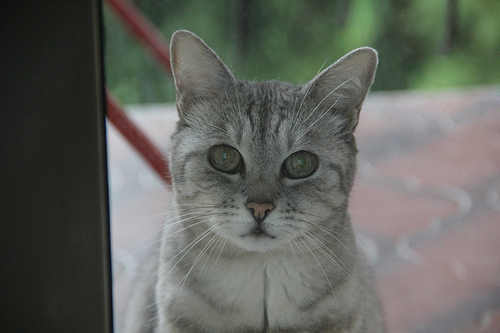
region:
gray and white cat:
[121, 38, 383, 332]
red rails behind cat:
[106, 8, 230, 194]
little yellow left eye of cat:
[203, 141, 250, 179]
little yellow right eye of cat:
[276, 137, 323, 188]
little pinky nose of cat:
[241, 190, 273, 224]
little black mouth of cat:
[246, 220, 278, 241]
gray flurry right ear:
[304, 47, 381, 113]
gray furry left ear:
[164, 25, 243, 106]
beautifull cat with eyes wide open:
[108, 34, 393, 332]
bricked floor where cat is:
[102, 77, 494, 330]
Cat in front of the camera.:
[151, 32, 387, 332]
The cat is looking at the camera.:
[153, 29, 381, 264]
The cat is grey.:
[148, 28, 395, 330]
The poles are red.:
[106, 0, 175, 187]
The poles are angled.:
[104, 1, 180, 175]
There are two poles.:
[100, 0, 175, 201]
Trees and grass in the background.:
[108, 3, 498, 80]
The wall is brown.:
[1, 8, 108, 332]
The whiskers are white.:
[138, 205, 212, 297]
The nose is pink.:
[241, 191, 283, 231]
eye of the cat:
[186, 136, 338, 188]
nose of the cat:
[241, 195, 295, 228]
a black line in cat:
[242, 242, 288, 331]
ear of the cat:
[311, 25, 415, 142]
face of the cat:
[152, 37, 436, 314]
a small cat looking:
[163, 40, 418, 280]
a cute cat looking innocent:
[120, 22, 444, 309]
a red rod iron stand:
[96, 91, 195, 182]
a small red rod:
[117, 12, 334, 304]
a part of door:
[12, 11, 141, 329]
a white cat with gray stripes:
[103, 25, 407, 328]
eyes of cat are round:
[196, 133, 326, 193]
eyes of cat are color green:
[200, 137, 324, 186]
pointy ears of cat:
[161, 22, 384, 134]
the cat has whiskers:
[137, 199, 367, 284]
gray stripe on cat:
[223, 83, 296, 142]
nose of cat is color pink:
[243, 193, 276, 225]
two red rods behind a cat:
[104, 8, 213, 213]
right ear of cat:
[303, 37, 384, 132]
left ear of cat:
[159, 20, 242, 112]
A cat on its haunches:
[195, 93, 335, 251]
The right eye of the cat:
[213, 151, 235, 169]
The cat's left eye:
[290, 157, 310, 172]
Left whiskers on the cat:
[310, 228, 335, 245]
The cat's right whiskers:
[192, 247, 215, 264]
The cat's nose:
[251, 206, 268, 216]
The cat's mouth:
[255, 231, 262, 236]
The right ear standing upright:
[176, 43, 198, 78]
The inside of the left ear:
[337, 67, 359, 94]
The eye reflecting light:
[297, 158, 304, 166]